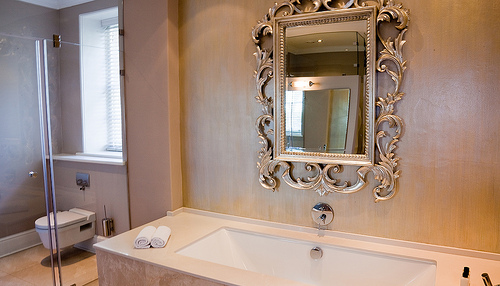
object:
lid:
[31, 207, 87, 230]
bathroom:
[1, 0, 498, 283]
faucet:
[310, 199, 334, 231]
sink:
[173, 224, 440, 284]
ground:
[443, 165, 474, 192]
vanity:
[89, 203, 494, 283]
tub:
[206, 236, 427, 275]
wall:
[0, 0, 60, 238]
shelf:
[93, 214, 498, 281]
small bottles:
[455, 264, 474, 286]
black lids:
[458, 263, 472, 281]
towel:
[132, 223, 155, 248]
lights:
[291, 80, 318, 89]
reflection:
[283, 21, 368, 157]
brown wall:
[120, 0, 499, 253]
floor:
[26, 252, 90, 279]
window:
[78, 9, 128, 159]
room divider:
[0, 1, 131, 284]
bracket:
[52, 32, 62, 47]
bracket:
[117, 27, 126, 38]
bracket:
[118, 67, 127, 78]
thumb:
[33, 204, 97, 248]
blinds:
[96, 13, 123, 153]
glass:
[280, 19, 363, 155]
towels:
[150, 222, 171, 249]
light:
[291, 77, 315, 87]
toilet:
[34, 203, 94, 248]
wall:
[47, 158, 126, 233]